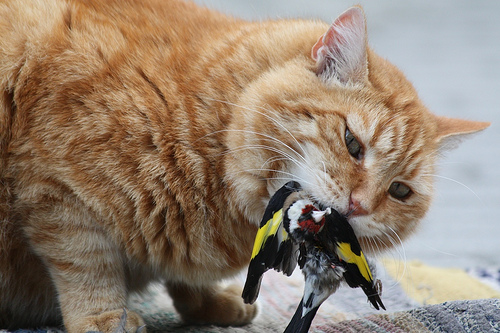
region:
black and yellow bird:
[233, 182, 384, 332]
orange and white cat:
[2, 2, 489, 328]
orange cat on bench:
[2, 1, 489, 331]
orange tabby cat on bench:
[1, 2, 487, 329]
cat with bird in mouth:
[1, 1, 491, 330]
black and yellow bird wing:
[325, 214, 387, 311]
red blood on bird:
[299, 205, 319, 230]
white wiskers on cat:
[212, 118, 334, 201]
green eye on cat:
[343, 128, 362, 157]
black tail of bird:
[281, 301, 318, 331]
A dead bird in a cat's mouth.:
[249, 173, 391, 306]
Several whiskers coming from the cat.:
[217, 92, 338, 205]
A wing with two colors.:
[233, 208, 283, 296]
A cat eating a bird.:
[5, 1, 452, 310]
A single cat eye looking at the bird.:
[333, 120, 365, 162]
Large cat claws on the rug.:
[52, 295, 154, 331]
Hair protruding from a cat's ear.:
[327, 25, 366, 77]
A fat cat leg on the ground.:
[27, 199, 144, 326]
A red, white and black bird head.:
[289, 195, 327, 250]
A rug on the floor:
[417, 238, 477, 323]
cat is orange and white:
[251, 35, 436, 241]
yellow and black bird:
[250, 165, 360, 325]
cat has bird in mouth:
[165, 0, 470, 325]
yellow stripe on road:
[385, 235, 495, 291]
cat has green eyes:
[335, 86, 407, 188]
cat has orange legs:
[15, 192, 140, 312]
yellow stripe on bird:
[242, 175, 392, 282]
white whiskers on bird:
[200, 75, 420, 320]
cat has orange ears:
[312, 4, 472, 176]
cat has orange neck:
[69, 23, 267, 139]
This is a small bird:
[248, 145, 390, 330]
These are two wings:
[71, 166, 163, 267]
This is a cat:
[129, 223, 184, 298]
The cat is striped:
[94, 138, 206, 247]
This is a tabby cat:
[108, 185, 233, 323]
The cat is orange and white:
[106, 191, 182, 251]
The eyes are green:
[300, 120, 440, 205]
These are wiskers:
[278, 168, 358, 204]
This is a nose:
[360, 192, 393, 249]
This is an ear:
[288, 36, 455, 133]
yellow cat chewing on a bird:
[1, 0, 493, 332]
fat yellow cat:
[1, 2, 492, 330]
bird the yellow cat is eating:
[232, 178, 388, 331]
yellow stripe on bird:
[251, 210, 286, 261]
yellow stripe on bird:
[333, 239, 375, 284]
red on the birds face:
[295, 202, 323, 233]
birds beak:
[308, 203, 332, 225]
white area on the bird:
[301, 269, 329, 316]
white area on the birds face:
[289, 197, 313, 232]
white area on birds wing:
[279, 183, 290, 254]